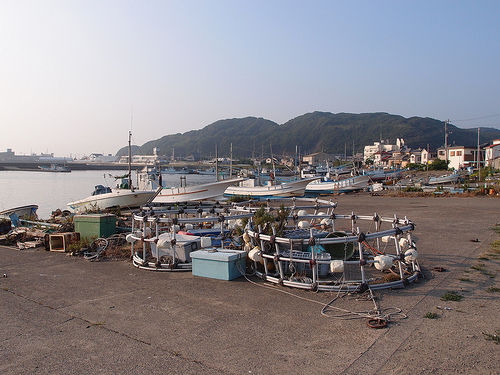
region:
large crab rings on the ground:
[128, 200, 423, 289]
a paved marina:
[1, 192, 498, 373]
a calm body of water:
[0, 167, 275, 217]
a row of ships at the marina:
[68, 142, 461, 217]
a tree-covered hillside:
[116, 110, 499, 155]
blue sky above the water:
[1, 0, 499, 161]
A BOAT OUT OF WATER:
[71, 168, 153, 234]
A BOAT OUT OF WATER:
[169, 180, 246, 228]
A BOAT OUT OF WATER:
[234, 158, 300, 218]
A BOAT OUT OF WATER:
[307, 165, 387, 194]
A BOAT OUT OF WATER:
[432, 153, 462, 188]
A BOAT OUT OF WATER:
[130, 145, 167, 172]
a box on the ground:
[187, 238, 249, 291]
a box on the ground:
[62, 209, 112, 251]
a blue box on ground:
[179, 233, 265, 307]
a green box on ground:
[59, 208, 131, 250]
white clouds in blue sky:
[15, 21, 93, 69]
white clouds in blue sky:
[405, 48, 439, 96]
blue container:
[182, 238, 236, 295]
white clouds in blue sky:
[112, 41, 123, 68]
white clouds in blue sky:
[188, 95, 266, 127]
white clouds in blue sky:
[92, 46, 132, 94]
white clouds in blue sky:
[232, 12, 280, 74]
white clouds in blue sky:
[105, 59, 127, 83]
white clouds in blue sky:
[170, 59, 238, 110]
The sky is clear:
[3, 76, 498, 146]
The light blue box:
[186, 244, 246, 291]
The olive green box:
[67, 206, 115, 243]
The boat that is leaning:
[65, 173, 166, 214]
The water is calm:
[0, 170, 301, 212]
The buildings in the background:
[363, 137, 495, 164]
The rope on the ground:
[325, 291, 399, 341]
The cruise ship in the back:
[117, 139, 162, 166]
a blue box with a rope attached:
[187, 242, 254, 287]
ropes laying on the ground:
[316, 289, 411, 323]